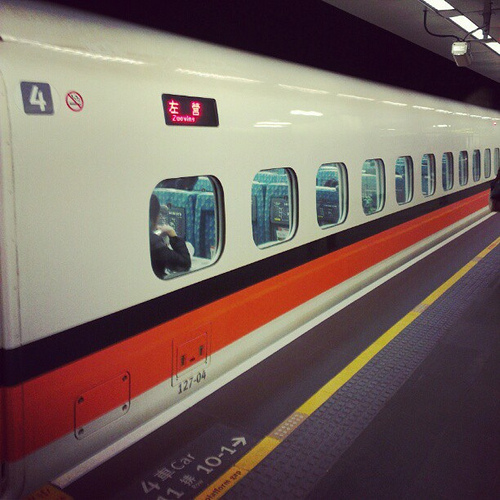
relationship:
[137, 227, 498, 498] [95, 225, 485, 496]
line on platform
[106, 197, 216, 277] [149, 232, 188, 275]
person wearing top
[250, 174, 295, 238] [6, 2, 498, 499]
sits of train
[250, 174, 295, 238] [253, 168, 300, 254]
sits through window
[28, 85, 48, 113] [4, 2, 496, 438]
number on side of train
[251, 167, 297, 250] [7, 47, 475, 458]
glass window on side of train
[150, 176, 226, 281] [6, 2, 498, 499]
glass window on side of train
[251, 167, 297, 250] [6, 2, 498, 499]
glass window on side of train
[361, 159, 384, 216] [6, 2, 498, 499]
glass window on side of train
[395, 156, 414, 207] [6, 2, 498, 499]
glass window on side of train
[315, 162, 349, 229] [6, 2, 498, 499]
glass window on side of train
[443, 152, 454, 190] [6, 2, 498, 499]
window on side of train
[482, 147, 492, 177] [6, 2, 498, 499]
window on side of train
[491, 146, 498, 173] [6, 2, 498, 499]
window on side of train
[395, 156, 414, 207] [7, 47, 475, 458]
glass window on side of train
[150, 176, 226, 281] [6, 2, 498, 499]
glass window on train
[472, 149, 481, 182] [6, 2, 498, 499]
window on train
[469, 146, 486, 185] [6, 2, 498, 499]
window on train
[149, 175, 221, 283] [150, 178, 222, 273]
glass panes on glass window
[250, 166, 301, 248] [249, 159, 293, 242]
glass panes on glass window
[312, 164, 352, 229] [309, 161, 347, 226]
glass panes on glass window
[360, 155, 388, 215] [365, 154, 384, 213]
glass panes on glass window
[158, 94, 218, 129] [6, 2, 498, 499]
signage on train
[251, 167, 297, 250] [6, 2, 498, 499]
glass window on train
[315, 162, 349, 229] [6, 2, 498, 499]
glass window on train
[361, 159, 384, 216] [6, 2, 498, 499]
glass window on train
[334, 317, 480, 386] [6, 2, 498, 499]
black line on train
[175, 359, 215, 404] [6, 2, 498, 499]
number on train